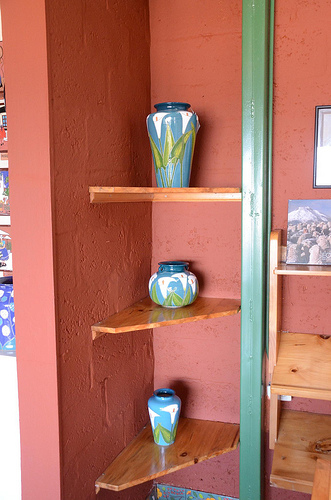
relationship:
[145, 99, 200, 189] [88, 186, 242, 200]
vase on a shelf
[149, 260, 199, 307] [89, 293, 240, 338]
vase on a shelf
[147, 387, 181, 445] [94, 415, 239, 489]
vase on a shelf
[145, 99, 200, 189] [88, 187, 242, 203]
vase on top shelf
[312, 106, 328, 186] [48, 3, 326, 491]
picture on wall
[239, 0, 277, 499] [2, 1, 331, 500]
green post on brick wall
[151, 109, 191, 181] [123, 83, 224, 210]
flowers on vase.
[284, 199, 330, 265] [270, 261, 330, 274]
picture on shelf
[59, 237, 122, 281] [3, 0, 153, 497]
holes in wall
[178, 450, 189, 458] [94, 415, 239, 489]
knot on shelf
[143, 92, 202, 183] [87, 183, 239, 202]
vase on shelf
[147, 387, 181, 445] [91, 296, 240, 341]
vase on shelf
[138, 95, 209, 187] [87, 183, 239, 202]
flower pot on shelf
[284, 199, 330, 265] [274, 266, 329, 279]
picture on shelf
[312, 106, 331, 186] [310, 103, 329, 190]
picture in frame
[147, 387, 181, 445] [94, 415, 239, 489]
vase in shelf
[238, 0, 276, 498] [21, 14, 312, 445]
beam on shelf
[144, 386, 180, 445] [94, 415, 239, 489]
vase on bottom shelf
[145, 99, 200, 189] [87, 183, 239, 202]
vase on shelf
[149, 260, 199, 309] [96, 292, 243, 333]
vase on shelf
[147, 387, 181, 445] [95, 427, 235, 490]
vase on shelf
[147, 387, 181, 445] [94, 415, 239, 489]
vase on shelf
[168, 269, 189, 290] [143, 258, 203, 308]
lilies on vase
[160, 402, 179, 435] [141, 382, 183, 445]
lilies on vase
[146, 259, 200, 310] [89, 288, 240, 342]
pot on shelf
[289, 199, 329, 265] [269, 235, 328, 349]
picture on shelf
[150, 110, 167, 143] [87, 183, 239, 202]
lilies on shelf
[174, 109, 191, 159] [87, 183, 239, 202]
lilies on shelf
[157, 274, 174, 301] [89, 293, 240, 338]
lilies on shelf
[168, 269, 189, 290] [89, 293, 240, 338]
lilies on shelf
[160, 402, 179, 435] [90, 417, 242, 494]
lilies on shelf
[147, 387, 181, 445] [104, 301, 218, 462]
vase on shelf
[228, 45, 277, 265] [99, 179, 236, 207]
green post next to shelves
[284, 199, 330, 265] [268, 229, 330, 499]
picture on shelf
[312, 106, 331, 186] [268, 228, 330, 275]
picture above shelf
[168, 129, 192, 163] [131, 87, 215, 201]
leaf on vase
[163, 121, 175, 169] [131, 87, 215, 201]
leaf on vase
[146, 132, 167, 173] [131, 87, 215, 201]
leaf on vase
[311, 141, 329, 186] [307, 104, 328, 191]
light shining on picture